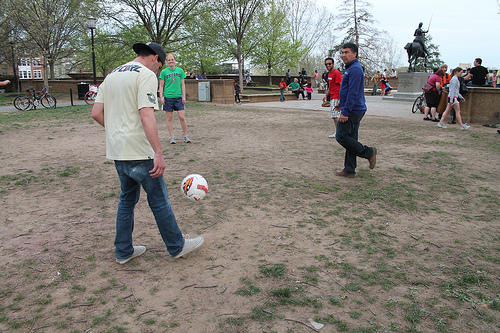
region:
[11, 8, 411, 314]
a pickup soccer game in a park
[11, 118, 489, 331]
the grass cover in this park is extremely sad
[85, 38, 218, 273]
the guy with the ball has kicked it into the air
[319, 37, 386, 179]
two more pickup soccer players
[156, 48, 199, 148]
this pickup soccer player is wearing a green t-shirt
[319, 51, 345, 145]
this soccer player is wearing a red t-shirt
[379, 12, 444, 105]
statue of somebody important astride a horse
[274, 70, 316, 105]
parkgoers gathered at a low bench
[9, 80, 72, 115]
bicycles parked at the edge of the sad grassy area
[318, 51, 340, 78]
this soccer player is wearing sunglasses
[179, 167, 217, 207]
a white and red soccer ball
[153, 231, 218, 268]
white shoe on right foot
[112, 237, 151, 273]
white shoe on the left foot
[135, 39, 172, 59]
hat on the man's head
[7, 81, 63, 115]
bike in the background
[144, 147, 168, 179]
the man's right hand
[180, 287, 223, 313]
patch of dirt on the ground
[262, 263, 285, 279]
patch of green grass on the ground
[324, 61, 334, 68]
glasses on the man's face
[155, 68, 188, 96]
the man's green shirt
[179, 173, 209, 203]
A white and red soccer ball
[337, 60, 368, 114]
Man is wearing a blue shirt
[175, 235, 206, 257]
Man is wearing white shoes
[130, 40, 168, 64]
The hat is backwards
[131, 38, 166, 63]
The hat is dark blue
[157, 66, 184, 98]
The person is wearing a green shirt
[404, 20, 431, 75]
Statue of a man on a horse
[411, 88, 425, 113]
A bike tire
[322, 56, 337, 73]
Man is wearing sunglasses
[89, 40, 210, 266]
Man is kicking soccer ball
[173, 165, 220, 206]
soccer ball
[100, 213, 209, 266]
pair of grey sneakers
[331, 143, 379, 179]
pair of brown boots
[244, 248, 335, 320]
grass patches on ground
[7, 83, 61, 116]
bicycles leaning on tree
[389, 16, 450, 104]
statue on concrete foundation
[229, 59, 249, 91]
tree trunk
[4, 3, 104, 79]
tree on side of green field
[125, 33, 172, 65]
black baseball cap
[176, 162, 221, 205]
soccer ball in the air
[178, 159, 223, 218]
soccer ball off the ground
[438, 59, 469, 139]
lady with a ponytail walking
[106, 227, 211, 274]
gray canvas man's shoes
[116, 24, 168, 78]
person wearing cap backwards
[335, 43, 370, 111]
man with long sleeve shirt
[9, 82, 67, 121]
bicycles parked on grass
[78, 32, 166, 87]
writing on the back of a tshirt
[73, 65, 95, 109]
black trashcan on the ground